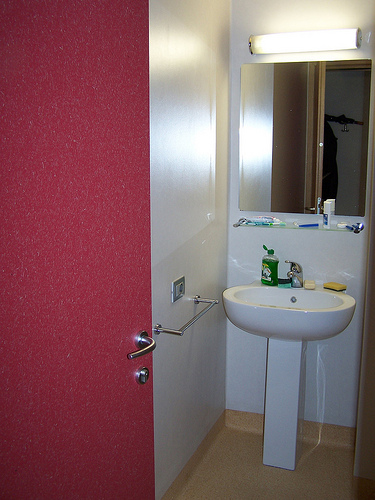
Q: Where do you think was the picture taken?
A: It was taken at the bathroom.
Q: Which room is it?
A: It is a bathroom.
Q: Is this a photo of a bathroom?
A: Yes, it is showing a bathroom.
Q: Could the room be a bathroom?
A: Yes, it is a bathroom.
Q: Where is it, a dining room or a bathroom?
A: It is a bathroom.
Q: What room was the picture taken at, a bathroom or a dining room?
A: It was taken at a bathroom.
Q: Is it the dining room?
A: No, it is the bathroom.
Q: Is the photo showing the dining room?
A: No, the picture is showing the bathroom.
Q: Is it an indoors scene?
A: Yes, it is indoors.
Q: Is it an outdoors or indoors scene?
A: It is indoors.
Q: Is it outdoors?
A: No, it is indoors.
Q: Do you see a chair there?
A: No, there are no chairs.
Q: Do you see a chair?
A: No, there are no chairs.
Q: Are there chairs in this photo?
A: No, there are no chairs.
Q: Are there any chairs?
A: No, there are no chairs.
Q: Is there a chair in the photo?
A: No, there are no chairs.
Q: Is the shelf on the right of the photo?
A: Yes, the shelf is on the right of the image.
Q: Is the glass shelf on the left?
A: No, the shelf is on the right of the image.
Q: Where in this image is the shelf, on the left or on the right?
A: The shelf is on the right of the image.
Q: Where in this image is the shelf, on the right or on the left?
A: The shelf is on the right of the image.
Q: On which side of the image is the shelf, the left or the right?
A: The shelf is on the right of the image.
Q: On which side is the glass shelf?
A: The shelf is on the right of the image.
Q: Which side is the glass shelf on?
A: The shelf is on the right of the image.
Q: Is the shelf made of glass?
A: Yes, the shelf is made of glass.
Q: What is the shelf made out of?
A: The shelf is made of glass.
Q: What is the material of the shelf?
A: The shelf is made of glass.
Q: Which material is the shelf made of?
A: The shelf is made of glass.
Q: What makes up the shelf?
A: The shelf is made of glass.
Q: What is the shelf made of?
A: The shelf is made of glass.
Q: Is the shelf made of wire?
A: No, the shelf is made of glass.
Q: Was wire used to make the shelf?
A: No, the shelf is made of glass.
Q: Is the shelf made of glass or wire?
A: The shelf is made of glass.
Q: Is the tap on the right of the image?
A: Yes, the tap is on the right of the image.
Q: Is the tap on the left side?
A: No, the tap is on the right of the image.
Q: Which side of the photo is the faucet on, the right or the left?
A: The faucet is on the right of the image.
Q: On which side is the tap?
A: The tap is on the right of the image.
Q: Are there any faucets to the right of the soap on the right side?
A: Yes, there is a faucet to the right of the soap.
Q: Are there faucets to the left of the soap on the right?
A: No, the faucet is to the right of the soap.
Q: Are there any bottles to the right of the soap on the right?
A: No, there is a faucet to the right of the soap.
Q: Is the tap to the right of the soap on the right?
A: Yes, the tap is to the right of the soap.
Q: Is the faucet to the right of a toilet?
A: No, the faucet is to the right of the soap.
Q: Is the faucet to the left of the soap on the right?
A: No, the faucet is to the right of the soap.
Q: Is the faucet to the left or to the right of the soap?
A: The faucet is to the right of the soap.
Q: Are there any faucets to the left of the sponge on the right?
A: Yes, there is a faucet to the left of the sponge.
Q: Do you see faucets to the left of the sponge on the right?
A: Yes, there is a faucet to the left of the sponge.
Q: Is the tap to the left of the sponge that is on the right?
A: Yes, the tap is to the left of the sponge.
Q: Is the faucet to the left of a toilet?
A: No, the faucet is to the left of the sponge.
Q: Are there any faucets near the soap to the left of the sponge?
A: Yes, there is a faucet near the soap.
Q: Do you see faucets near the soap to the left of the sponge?
A: Yes, there is a faucet near the soap.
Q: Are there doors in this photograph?
A: Yes, there is a door.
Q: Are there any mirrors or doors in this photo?
A: Yes, there is a door.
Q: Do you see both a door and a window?
A: No, there is a door but no windows.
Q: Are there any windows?
A: No, there are no windows.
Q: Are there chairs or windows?
A: No, there are no windows or chairs.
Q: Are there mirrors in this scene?
A: Yes, there is a mirror.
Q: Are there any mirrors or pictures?
A: Yes, there is a mirror.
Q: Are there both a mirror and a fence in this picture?
A: No, there is a mirror but no fences.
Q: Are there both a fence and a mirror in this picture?
A: No, there is a mirror but no fences.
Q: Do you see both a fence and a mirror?
A: No, there is a mirror but no fences.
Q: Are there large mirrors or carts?
A: Yes, there is a large mirror.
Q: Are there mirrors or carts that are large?
A: Yes, the mirror is large.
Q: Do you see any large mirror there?
A: Yes, there is a large mirror.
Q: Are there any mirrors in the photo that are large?
A: Yes, there is a mirror that is large.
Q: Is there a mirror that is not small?
A: Yes, there is a large mirror.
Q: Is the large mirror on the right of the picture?
A: Yes, the mirror is on the right of the image.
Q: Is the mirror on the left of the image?
A: No, the mirror is on the right of the image.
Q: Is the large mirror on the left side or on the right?
A: The mirror is on the right of the image.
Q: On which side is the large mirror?
A: The mirror is on the right of the image.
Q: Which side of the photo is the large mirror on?
A: The mirror is on the right of the image.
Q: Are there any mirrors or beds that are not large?
A: No, there is a mirror but it is large.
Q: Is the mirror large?
A: Yes, the mirror is large.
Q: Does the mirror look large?
A: Yes, the mirror is large.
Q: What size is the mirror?
A: The mirror is large.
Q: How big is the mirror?
A: The mirror is large.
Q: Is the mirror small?
A: No, the mirror is large.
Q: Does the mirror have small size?
A: No, the mirror is large.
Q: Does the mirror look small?
A: No, the mirror is large.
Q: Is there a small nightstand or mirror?
A: No, there is a mirror but it is large.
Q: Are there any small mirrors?
A: No, there is a mirror but it is large.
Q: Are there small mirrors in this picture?
A: No, there is a mirror but it is large.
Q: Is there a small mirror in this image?
A: No, there is a mirror but it is large.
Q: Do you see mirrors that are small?
A: No, there is a mirror but it is large.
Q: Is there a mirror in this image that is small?
A: No, there is a mirror but it is large.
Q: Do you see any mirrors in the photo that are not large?
A: No, there is a mirror but it is large.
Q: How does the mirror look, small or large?
A: The mirror is large.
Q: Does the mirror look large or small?
A: The mirror is large.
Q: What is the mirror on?
A: The mirror is on the wall.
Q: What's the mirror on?
A: The mirror is on the wall.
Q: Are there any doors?
A: Yes, there is a door.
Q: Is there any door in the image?
A: Yes, there is a door.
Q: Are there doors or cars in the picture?
A: Yes, there is a door.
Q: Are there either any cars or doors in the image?
A: Yes, there is a door.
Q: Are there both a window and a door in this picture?
A: No, there is a door but no windows.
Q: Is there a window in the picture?
A: No, there are no windows.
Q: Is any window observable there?
A: No, there are no windows.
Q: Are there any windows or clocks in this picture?
A: No, there are no windows or clocks.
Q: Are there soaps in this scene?
A: Yes, there is a soap.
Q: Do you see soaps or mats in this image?
A: Yes, there is a soap.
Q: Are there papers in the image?
A: No, there are no papers.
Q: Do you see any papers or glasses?
A: No, there are no papers or glasses.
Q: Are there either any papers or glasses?
A: No, there are no papers or glasses.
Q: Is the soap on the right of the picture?
A: Yes, the soap is on the right of the image.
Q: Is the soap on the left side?
A: No, the soap is on the right of the image.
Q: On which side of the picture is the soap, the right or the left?
A: The soap is on the right of the image.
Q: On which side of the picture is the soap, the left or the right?
A: The soap is on the right of the image.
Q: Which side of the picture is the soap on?
A: The soap is on the right of the image.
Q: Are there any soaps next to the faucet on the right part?
A: Yes, there is a soap next to the faucet.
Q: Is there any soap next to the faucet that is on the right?
A: Yes, there is a soap next to the faucet.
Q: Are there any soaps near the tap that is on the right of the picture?
A: Yes, there is a soap near the faucet.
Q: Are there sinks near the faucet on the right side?
A: No, there is a soap near the tap.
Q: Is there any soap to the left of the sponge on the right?
A: Yes, there is a soap to the left of the sponge.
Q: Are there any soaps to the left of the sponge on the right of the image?
A: Yes, there is a soap to the left of the sponge.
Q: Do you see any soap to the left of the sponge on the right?
A: Yes, there is a soap to the left of the sponge.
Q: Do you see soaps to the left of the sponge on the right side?
A: Yes, there is a soap to the left of the sponge.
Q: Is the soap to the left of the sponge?
A: Yes, the soap is to the left of the sponge.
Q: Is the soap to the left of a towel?
A: No, the soap is to the left of the sponge.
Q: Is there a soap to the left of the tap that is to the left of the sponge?
A: Yes, there is a soap to the left of the tap.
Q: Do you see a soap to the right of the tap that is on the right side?
A: No, the soap is to the left of the tap.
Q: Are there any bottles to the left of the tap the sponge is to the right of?
A: No, there is a soap to the left of the faucet.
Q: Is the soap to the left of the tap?
A: Yes, the soap is to the left of the tap.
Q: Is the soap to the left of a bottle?
A: No, the soap is to the left of the tap.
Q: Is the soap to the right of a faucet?
A: No, the soap is to the left of a faucet.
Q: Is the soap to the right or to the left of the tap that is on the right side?
A: The soap is to the left of the faucet.